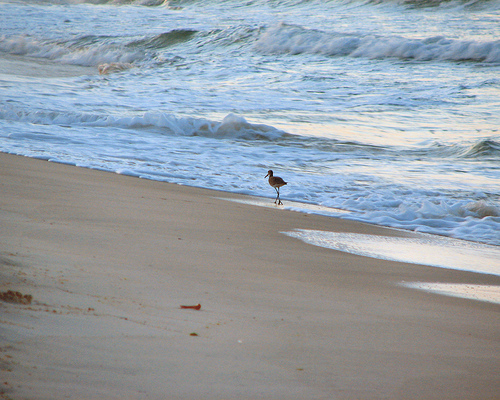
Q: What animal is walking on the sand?
A: A bird.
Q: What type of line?
A: Shore.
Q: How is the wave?
A: Foamy.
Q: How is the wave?
A: Crashing.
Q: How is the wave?
A: Gentle.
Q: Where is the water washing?
A: On sand.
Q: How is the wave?
A: Rising.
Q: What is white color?
A: Foam.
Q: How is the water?
A: Wavy.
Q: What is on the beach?
A: A bird.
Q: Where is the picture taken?
A: At a beach.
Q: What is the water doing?
A: Crashing on the shore.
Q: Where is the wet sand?
A: At the shoreline.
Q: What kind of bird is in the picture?
A: A sea bird.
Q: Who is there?
A: No one.